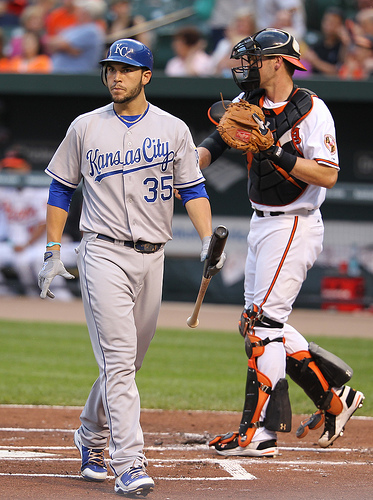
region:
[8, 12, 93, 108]
crowd in the bleachers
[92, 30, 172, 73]
batter's blue safety helmet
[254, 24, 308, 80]
catcher's black and orange safety helmet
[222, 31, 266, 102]
catcher's black safety mask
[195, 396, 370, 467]
catcher's black and white shoes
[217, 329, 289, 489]
catcher's black and orange shin guards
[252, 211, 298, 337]
orange stripe down white pants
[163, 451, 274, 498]
white markings on baseball field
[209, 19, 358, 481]
catcher in black orange and white uniform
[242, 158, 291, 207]
catcher's black chest protector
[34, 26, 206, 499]
baseball player in blue and grey uniform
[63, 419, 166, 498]
pair of blue and white baseball shoes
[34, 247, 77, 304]
batter's grey glove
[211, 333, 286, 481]
catcher;s black and orange shin guards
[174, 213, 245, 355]
baseball bat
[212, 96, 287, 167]
brown leather catcher's mitt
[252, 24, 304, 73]
catcher's black safety helmet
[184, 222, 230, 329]
A brown and black baseball bat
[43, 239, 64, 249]
A light blue wristband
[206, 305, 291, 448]
The leg guards of an umpire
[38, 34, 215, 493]
A batter from Kansas City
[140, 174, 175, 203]
The number 35 on a jersey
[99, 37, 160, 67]
A baseball bat's hat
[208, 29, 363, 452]
A baseball catcher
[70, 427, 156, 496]
A pair of white and blue shoes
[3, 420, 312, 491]
White lines on the baseball field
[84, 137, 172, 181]
A Kansas City logo on a jersey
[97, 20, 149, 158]
baseball player wearing a blue helmet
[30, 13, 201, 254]
baseball player wearing a long sleeve shirt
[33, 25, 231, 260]
base ball player wearing a gray uniform shirt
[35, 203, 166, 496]
base ball player wearing a gray pants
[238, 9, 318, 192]
base ball player wearing a black helmet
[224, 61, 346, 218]
base ball player wearing a white shirt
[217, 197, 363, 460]
base ball player wearing white pants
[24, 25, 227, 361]
base player holding a bat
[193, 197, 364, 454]
base ball wearing shin guards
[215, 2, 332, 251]
baseball player holding a glove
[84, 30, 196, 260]
Kansas City uniform on player.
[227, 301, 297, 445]
Protective knee and leg gear on leg.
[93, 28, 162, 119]
Blue helmet on player.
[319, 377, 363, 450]
Baseball cleats on feet.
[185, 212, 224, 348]
Black and brown colored baseball bat.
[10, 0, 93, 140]
Spectators watching from bleachers.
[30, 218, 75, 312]
Gray glove on hand.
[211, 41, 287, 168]
Catchers mitt on hand.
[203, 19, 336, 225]
Face mask on catcher.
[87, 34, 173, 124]
Groomed beard and mustache on player.